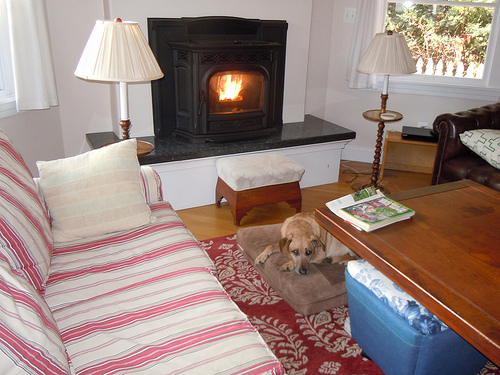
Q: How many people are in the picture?
A: None.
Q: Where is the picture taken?
A: Living room.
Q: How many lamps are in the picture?
A: Two.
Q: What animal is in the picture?
A: Dog.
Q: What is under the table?
A: Footrest.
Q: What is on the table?
A: Magazines.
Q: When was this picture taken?
A: Daytime.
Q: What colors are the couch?
A: White and pink.